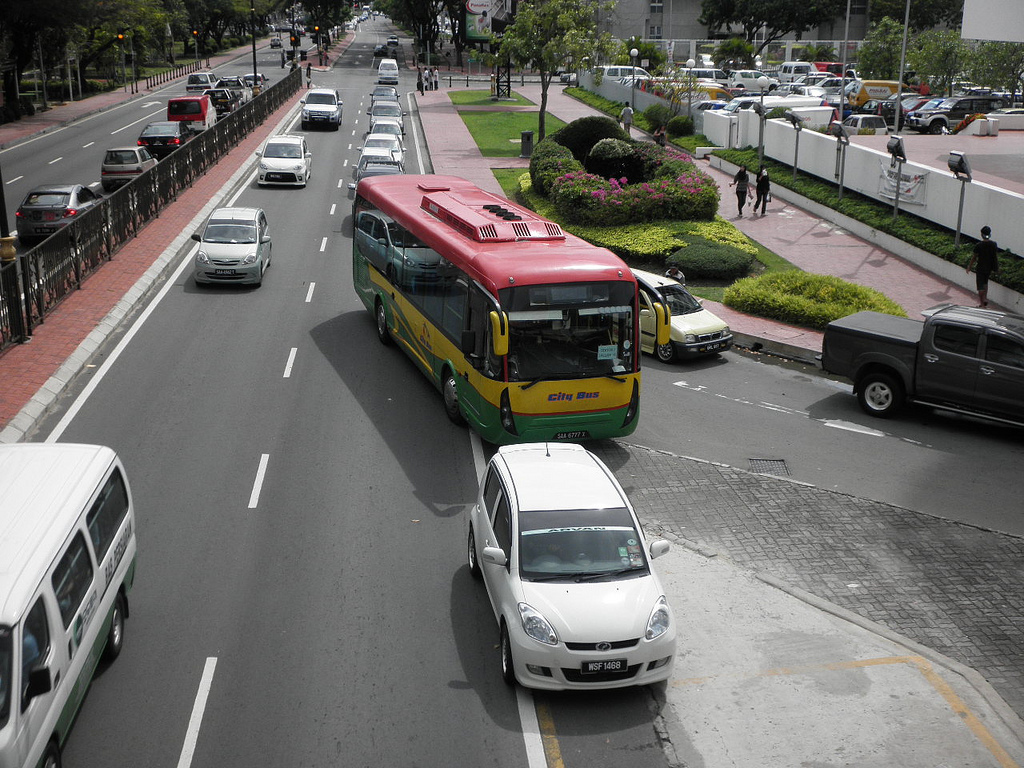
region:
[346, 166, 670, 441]
A colorful bus in the street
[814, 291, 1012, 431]
A pickup truck in the street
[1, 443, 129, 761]
A white van in the street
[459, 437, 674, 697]
A white car in the street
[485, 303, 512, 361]
Yellow mirrors on a bus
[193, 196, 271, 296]
Gray car in the street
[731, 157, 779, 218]
People walking on the sidewalk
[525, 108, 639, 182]
Shrubery in a median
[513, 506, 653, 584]
Windshield on a car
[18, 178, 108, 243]
car driving on street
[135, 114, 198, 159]
car driving on street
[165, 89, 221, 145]
car driving on street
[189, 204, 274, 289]
car driving on street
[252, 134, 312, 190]
car driving on street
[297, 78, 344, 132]
car driving on street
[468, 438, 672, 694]
car driving on street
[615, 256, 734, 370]
car driving on street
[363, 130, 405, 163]
car driving on street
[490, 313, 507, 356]
The right side mirror of a bus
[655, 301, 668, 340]
The left side mirror of a bus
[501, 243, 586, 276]
The front red roof of a bus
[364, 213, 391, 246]
A car reflection on the bus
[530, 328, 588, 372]
The windshield of a bus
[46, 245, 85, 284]
Steel barriers separating two sides of the road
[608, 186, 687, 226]
A flower bed on the side of the road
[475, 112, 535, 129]
A lawn of green grass on the roadside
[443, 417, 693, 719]
white car on the street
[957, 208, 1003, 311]
person walking on the sidewalk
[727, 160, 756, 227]
person walking on the sidewalk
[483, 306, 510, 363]
yellow mirror on the bus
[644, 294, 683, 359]
yellow mirror on the bus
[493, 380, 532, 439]
headlight on the bus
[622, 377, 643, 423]
headlight on the bus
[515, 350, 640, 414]
windshield wiper on the bus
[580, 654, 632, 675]
license plate on the car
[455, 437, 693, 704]
car parked on median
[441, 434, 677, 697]
parked car is small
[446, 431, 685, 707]
parked car is white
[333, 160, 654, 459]
bus turning on road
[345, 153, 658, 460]
bus is red yellow and green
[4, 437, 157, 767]
white van in right lane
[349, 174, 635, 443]
red green and yellow bus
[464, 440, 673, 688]
white sedan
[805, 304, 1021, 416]
black colored pick up truck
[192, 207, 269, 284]
silver car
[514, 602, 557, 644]
left headlight of car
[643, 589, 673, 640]
right headlight of car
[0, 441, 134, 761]
white and green van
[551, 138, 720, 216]
bush with pink flowers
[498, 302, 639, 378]
front windshield of a bus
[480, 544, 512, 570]
side mirror of a vehicle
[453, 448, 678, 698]
car parked on median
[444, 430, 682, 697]
parked car is white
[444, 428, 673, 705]
parked car is small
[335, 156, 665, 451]
bus turning on road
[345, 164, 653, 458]
bus is red yellow and green